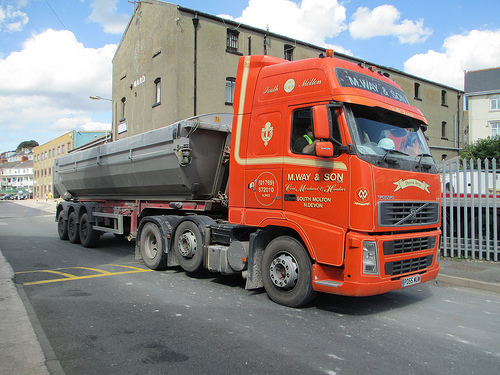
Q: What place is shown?
A: It is a road.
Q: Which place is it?
A: It is a road.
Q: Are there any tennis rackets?
A: No, there are no tennis rackets.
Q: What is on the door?
A: The logo is on the door.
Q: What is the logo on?
A: The logo is on the door.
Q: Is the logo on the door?
A: Yes, the logo is on the door.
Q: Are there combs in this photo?
A: No, there are no combs.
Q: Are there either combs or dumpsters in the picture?
A: No, there are no combs or dumpsters.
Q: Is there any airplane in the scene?
A: No, there are no airplanes.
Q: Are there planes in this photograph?
A: No, there are no planes.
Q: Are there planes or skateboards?
A: No, there are no planes or skateboards.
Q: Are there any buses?
A: No, there are no buses.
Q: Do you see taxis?
A: Yes, there is a taxi.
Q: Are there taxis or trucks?
A: Yes, there is a taxi.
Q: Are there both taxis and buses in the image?
A: No, there is a taxi but no buses.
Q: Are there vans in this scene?
A: No, there are no vans.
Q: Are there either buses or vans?
A: No, there are no vans or buses.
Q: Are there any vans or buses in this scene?
A: No, there are no vans or buses.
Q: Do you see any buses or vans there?
A: No, there are no vans or buses.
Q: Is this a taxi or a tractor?
A: This is a taxi.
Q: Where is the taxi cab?
A: The taxi cab is on the road.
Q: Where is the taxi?
A: The taxi cab is on the road.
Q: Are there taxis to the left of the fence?
A: Yes, there is a taxi to the left of the fence.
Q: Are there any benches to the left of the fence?
A: No, there is a taxi to the left of the fence.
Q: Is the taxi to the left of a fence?
A: Yes, the taxi is to the left of a fence.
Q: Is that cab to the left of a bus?
A: No, the cab is to the left of a fence.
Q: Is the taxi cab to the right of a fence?
A: No, the taxi cab is to the left of a fence.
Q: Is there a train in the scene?
A: No, there are no trains.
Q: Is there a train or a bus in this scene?
A: No, there are no trains or buses.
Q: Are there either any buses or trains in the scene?
A: No, there are no trains or buses.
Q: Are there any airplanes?
A: No, there are no airplanes.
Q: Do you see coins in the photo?
A: No, there are no coins.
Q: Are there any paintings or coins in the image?
A: No, there are no coins or paintings.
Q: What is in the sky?
A: The clouds are in the sky.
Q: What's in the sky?
A: The clouds are in the sky.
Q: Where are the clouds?
A: The clouds are in the sky.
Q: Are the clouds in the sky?
A: Yes, the clouds are in the sky.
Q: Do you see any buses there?
A: No, there are no buses.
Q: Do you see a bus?
A: No, there are no buses.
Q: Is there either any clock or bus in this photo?
A: No, there are no buses or clocks.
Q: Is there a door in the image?
A: Yes, there is a door.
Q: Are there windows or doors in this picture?
A: Yes, there is a door.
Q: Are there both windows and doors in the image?
A: Yes, there are both a door and a window.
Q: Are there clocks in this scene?
A: No, there are no clocks.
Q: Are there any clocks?
A: No, there are no clocks.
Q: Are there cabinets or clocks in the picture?
A: No, there are no clocks or cabinets.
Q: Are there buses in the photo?
A: No, there are no buses.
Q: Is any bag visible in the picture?
A: No, there are no bags.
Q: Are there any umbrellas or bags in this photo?
A: No, there are no bags or umbrellas.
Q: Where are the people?
A: The people are in the truck.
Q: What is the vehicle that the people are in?
A: The vehicle is a truck.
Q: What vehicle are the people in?
A: The people are in the truck.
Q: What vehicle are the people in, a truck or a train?
A: The people are in a truck.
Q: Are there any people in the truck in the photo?
A: Yes, there are people in the truck.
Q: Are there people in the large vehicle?
A: Yes, there are people in the truck.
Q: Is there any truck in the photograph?
A: Yes, there is a truck.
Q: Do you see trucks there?
A: Yes, there is a truck.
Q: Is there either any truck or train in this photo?
A: Yes, there is a truck.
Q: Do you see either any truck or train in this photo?
A: Yes, there is a truck.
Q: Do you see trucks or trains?
A: Yes, there is a truck.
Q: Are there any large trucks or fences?
A: Yes, there is a large truck.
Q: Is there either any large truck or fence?
A: Yes, there is a large truck.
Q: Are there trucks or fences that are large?
A: Yes, the truck is large.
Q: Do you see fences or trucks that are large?
A: Yes, the truck is large.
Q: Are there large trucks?
A: Yes, there is a large truck.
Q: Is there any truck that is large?
A: Yes, there is a truck that is large.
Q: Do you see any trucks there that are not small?
A: Yes, there is a large truck.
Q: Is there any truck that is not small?
A: Yes, there is a large truck.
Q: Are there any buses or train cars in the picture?
A: No, there are no buses or train cars.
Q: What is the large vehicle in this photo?
A: The vehicle is a truck.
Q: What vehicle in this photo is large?
A: The vehicle is a truck.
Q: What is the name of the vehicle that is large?
A: The vehicle is a truck.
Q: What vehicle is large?
A: The vehicle is a truck.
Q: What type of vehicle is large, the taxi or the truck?
A: The truck is large.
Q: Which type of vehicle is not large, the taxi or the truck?
A: The taxi is not large.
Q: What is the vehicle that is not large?
A: The vehicle is a taxi.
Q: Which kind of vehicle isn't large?
A: The vehicle is a taxi.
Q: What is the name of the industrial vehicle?
A: The vehicle is a truck.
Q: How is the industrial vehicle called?
A: The vehicle is a truck.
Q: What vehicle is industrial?
A: The vehicle is a truck.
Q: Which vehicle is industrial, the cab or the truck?
A: The truck is industrial.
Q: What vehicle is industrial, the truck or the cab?
A: The truck is industrial.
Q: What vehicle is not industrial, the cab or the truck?
A: The cab is not industrial.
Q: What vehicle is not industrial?
A: The vehicle is a taxi.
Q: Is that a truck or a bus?
A: That is a truck.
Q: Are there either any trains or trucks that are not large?
A: No, there is a truck but it is large.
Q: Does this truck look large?
A: Yes, the truck is large.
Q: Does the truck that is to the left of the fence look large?
A: Yes, the truck is large.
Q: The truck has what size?
A: The truck is large.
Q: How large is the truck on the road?
A: The truck is large.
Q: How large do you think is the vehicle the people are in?
A: The truck is large.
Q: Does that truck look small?
A: No, the truck is large.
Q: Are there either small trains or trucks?
A: No, there is a truck but it is large.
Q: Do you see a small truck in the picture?
A: No, there is a truck but it is large.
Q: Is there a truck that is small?
A: No, there is a truck but it is large.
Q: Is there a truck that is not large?
A: No, there is a truck but it is large.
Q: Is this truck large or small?
A: The truck is large.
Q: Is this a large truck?
A: Yes, this is a large truck.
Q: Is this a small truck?
A: No, this is a large truck.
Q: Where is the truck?
A: The truck is on the road.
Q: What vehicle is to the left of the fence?
A: The vehicle is a truck.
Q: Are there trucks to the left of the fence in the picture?
A: Yes, there is a truck to the left of the fence.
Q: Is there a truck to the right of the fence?
A: No, the truck is to the left of the fence.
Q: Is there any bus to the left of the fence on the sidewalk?
A: No, there is a truck to the left of the fence.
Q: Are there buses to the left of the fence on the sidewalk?
A: No, there is a truck to the left of the fence.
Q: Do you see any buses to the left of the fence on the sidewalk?
A: No, there is a truck to the left of the fence.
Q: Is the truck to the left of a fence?
A: Yes, the truck is to the left of a fence.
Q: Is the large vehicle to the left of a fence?
A: Yes, the truck is to the left of a fence.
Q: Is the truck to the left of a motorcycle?
A: No, the truck is to the left of a fence.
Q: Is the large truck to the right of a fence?
A: No, the truck is to the left of a fence.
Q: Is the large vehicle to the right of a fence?
A: No, the truck is to the left of a fence.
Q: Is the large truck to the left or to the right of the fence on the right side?
A: The truck is to the left of the fence.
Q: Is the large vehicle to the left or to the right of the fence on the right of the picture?
A: The truck is to the left of the fence.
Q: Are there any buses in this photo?
A: No, there are no buses.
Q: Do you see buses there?
A: No, there are no buses.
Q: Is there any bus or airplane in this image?
A: No, there are no buses or airplanes.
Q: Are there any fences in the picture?
A: Yes, there is a fence.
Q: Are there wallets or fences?
A: Yes, there is a fence.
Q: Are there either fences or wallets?
A: Yes, there is a fence.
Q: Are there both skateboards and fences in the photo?
A: No, there is a fence but no skateboards.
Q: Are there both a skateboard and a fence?
A: No, there is a fence but no skateboards.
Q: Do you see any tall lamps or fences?
A: Yes, there is a tall fence.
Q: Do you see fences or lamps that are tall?
A: Yes, the fence is tall.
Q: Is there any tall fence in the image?
A: Yes, there is a tall fence.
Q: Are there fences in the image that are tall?
A: Yes, there is a fence that is tall.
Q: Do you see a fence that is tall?
A: Yes, there is a fence that is tall.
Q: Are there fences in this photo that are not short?
A: Yes, there is a tall fence.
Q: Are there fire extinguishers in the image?
A: No, there are no fire extinguishers.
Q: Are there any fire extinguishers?
A: No, there are no fire extinguishers.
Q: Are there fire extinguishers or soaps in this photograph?
A: No, there are no fire extinguishers or soaps.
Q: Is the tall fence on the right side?
A: Yes, the fence is on the right of the image.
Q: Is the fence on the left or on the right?
A: The fence is on the right of the image.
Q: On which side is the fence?
A: The fence is on the right of the image.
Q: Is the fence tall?
A: Yes, the fence is tall.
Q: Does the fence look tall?
A: Yes, the fence is tall.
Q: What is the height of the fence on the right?
A: The fence is tall.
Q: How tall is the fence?
A: The fence is tall.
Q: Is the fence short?
A: No, the fence is tall.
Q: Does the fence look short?
A: No, the fence is tall.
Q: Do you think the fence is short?
A: No, the fence is tall.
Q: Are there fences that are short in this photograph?
A: No, there is a fence but it is tall.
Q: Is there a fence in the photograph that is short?
A: No, there is a fence but it is tall.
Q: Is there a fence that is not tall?
A: No, there is a fence but it is tall.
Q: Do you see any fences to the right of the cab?
A: Yes, there is a fence to the right of the cab.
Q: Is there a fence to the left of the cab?
A: No, the fence is to the right of the cab.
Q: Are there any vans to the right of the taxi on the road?
A: No, there is a fence to the right of the taxi cab.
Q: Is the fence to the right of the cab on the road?
A: Yes, the fence is to the right of the taxi.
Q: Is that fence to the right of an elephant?
A: No, the fence is to the right of the taxi.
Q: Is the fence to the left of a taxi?
A: No, the fence is to the right of a taxi.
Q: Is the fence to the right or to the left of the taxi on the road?
A: The fence is to the right of the cab.